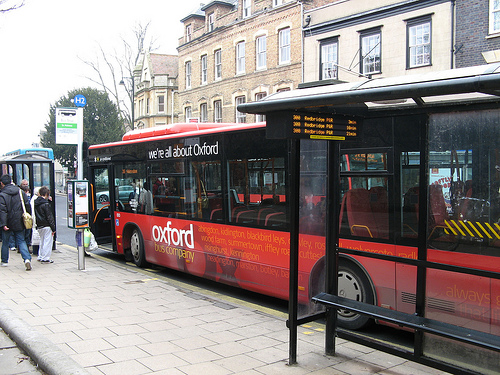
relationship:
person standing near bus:
[34, 185, 63, 265] [82, 135, 277, 283]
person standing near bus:
[3, 172, 35, 270] [82, 135, 277, 283]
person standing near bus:
[17, 178, 35, 255] [82, 135, 277, 283]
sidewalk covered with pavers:
[3, 248, 473, 372] [2, 242, 452, 373]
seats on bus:
[158, 189, 470, 234] [82, 95, 500, 353]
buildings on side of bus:
[129, 2, 499, 124] [82, 99, 499, 332]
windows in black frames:
[283, 26, 449, 69] [297, 24, 347, 73]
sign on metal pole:
[39, 95, 99, 148] [70, 147, 92, 184]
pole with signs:
[53, 91, 91, 271] [48, 95, 104, 168]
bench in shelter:
[295, 266, 453, 348] [228, 91, 456, 361]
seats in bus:
[159, 182, 466, 252] [78, 120, 298, 300]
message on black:
[140, 144, 228, 166] [94, 137, 266, 160]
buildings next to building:
[129, 0, 500, 131] [174, 0, 307, 135]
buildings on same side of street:
[129, 0, 500, 131] [71, 227, 469, 334]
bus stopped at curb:
[82, 95, 500, 353] [3, 234, 293, 371]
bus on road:
[84, 118, 499, 373] [49, 187, 138, 257]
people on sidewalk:
[3, 169, 103, 264] [36, 282, 228, 365]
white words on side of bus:
[148, 216, 197, 248] [87, 117, 300, 311]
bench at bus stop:
[310, 291, 499, 375] [238, 69, 493, 372]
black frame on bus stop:
[3, 155, 59, 250] [6, 155, 58, 265]